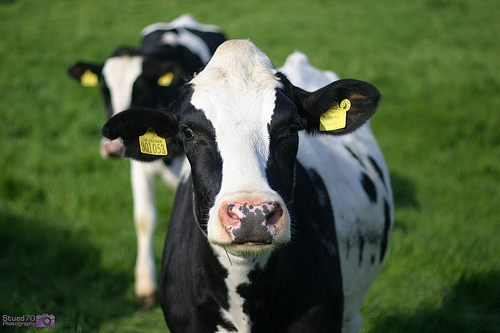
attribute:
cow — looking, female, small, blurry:
[64, 10, 229, 311]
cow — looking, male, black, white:
[99, 35, 398, 330]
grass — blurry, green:
[2, 1, 484, 329]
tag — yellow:
[78, 65, 99, 87]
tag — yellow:
[154, 70, 175, 87]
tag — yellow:
[317, 95, 352, 133]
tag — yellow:
[136, 125, 169, 156]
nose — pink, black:
[215, 194, 287, 235]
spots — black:
[343, 142, 397, 258]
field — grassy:
[395, 27, 493, 262]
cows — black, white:
[56, 4, 406, 331]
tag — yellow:
[133, 127, 170, 160]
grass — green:
[420, 41, 485, 218]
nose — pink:
[219, 194, 250, 225]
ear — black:
[296, 68, 386, 142]